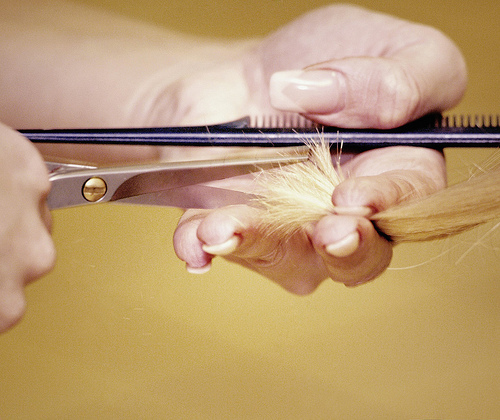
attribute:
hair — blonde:
[240, 123, 498, 269]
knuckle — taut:
[368, 57, 424, 129]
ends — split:
[265, 143, 322, 238]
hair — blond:
[267, 145, 499, 232]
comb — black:
[2, 107, 499, 152]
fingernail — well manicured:
[269, 68, 347, 119]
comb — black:
[10, 105, 498, 171]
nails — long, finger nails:
[163, 199, 375, 276]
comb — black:
[18, 115, 498, 147]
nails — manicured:
[183, 232, 360, 277]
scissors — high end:
[48, 147, 318, 221]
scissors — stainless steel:
[44, 153, 314, 219]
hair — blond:
[243, 139, 493, 251]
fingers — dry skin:
[177, 9, 469, 294]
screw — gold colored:
[81, 174, 109, 201]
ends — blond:
[259, 154, 334, 222]